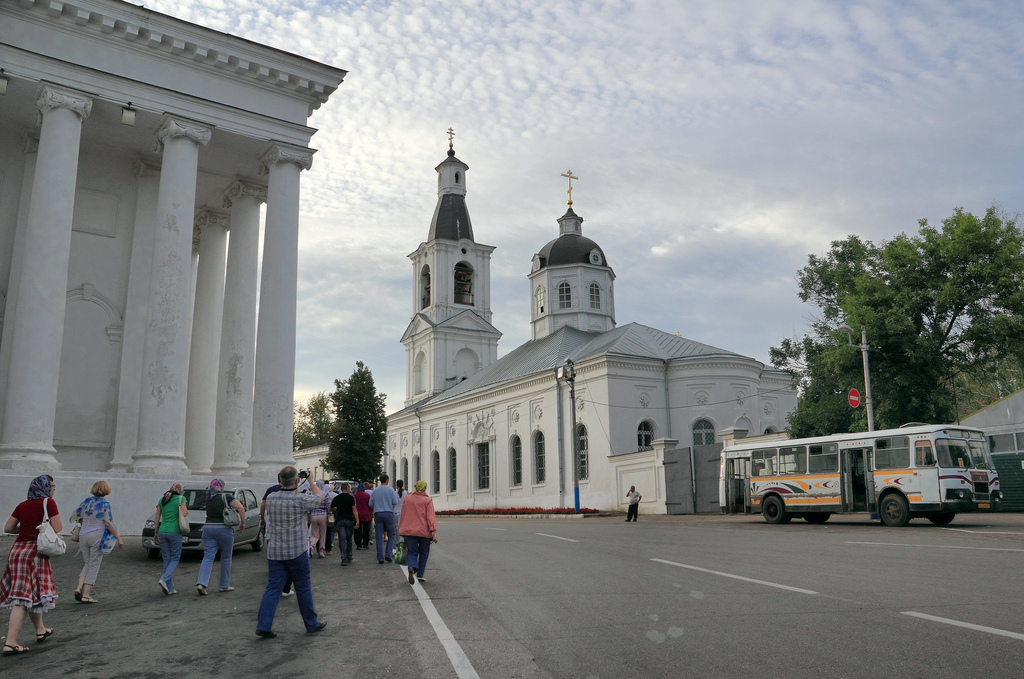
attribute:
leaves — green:
[793, 351, 841, 425]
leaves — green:
[872, 322, 912, 403]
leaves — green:
[816, 240, 883, 325]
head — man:
[272, 459, 301, 485]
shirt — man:
[250, 482, 331, 567]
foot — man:
[250, 619, 287, 641]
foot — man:
[294, 616, 327, 642]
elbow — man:
[302, 485, 328, 511]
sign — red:
[842, 381, 868, 407]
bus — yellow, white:
[719, 433, 987, 529]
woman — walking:
[149, 474, 189, 600]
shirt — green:
[149, 493, 189, 530]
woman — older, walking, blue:
[67, 474, 126, 600]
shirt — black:
[335, 493, 357, 533]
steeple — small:
[555, 191, 588, 231]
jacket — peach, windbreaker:
[391, 489, 450, 537]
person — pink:
[391, 471, 439, 567]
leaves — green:
[777, 210, 1020, 416]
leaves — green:
[770, 216, 1023, 431]